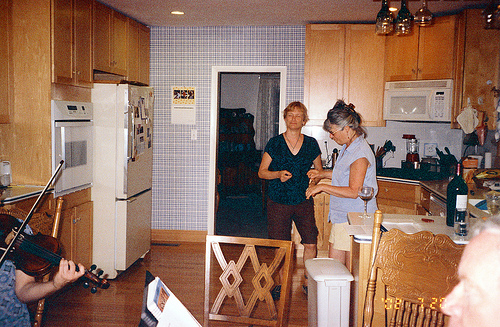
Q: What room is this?
A: It is a kitchen.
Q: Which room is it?
A: It is a kitchen.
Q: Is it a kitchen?
A: Yes, it is a kitchen.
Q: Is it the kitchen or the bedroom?
A: It is the kitchen.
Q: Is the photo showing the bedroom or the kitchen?
A: It is showing the kitchen.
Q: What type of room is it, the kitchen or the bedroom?
A: It is the kitchen.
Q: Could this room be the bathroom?
A: No, it is the kitchen.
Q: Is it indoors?
A: Yes, it is indoors.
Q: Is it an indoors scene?
A: Yes, it is indoors.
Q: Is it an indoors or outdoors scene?
A: It is indoors.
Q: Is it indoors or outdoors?
A: It is indoors.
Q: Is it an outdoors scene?
A: No, it is indoors.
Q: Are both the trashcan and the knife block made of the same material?
A: No, the trashcan is made of plastic and the knife block is made of wood.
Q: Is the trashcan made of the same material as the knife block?
A: No, the trashcan is made of plastic and the knife block is made of wood.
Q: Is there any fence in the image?
A: No, there are no fences.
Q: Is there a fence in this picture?
A: No, there are no fences.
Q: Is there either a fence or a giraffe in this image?
A: No, there are no fences or giraffes.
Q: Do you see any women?
A: Yes, there is a woman.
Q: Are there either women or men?
A: Yes, there is a woman.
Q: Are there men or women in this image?
A: Yes, there is a woman.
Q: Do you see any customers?
A: No, there are no customers.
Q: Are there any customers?
A: No, there are no customers.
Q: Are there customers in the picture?
A: No, there are no customers.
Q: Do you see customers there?
A: No, there are no customers.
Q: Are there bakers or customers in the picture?
A: No, there are no customers or bakers.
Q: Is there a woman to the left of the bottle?
A: Yes, there is a woman to the left of the bottle.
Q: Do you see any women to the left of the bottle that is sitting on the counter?
A: Yes, there is a woman to the left of the bottle.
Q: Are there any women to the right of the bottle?
A: No, the woman is to the left of the bottle.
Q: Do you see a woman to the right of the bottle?
A: No, the woman is to the left of the bottle.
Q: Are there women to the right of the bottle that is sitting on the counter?
A: No, the woman is to the left of the bottle.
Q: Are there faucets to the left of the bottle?
A: No, there is a woman to the left of the bottle.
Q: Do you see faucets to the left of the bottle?
A: No, there is a woman to the left of the bottle.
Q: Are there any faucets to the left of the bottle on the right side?
A: No, there is a woman to the left of the bottle.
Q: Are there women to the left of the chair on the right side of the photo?
A: Yes, there is a woman to the left of the chair.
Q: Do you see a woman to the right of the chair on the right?
A: No, the woman is to the left of the chair.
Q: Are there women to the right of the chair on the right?
A: No, the woman is to the left of the chair.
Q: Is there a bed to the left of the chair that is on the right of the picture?
A: No, there is a woman to the left of the chair.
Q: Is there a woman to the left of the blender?
A: Yes, there is a woman to the left of the blender.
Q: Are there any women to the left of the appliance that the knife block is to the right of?
A: Yes, there is a woman to the left of the blender.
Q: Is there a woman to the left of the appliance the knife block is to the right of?
A: Yes, there is a woman to the left of the blender.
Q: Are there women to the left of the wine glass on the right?
A: Yes, there is a woman to the left of the wine glass.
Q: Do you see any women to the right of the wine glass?
A: No, the woman is to the left of the wine glass.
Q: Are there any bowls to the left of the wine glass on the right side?
A: No, there is a woman to the left of the wine glass.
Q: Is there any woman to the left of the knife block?
A: Yes, there is a woman to the left of the knife block.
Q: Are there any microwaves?
A: Yes, there is a microwave.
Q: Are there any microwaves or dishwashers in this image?
A: Yes, there is a microwave.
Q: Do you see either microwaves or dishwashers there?
A: Yes, there is a microwave.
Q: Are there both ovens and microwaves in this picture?
A: Yes, there are both a microwave and an oven.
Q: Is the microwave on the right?
A: Yes, the microwave is on the right of the image.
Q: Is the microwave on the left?
A: No, the microwave is on the right of the image.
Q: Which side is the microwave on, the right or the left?
A: The microwave is on the right of the image.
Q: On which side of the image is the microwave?
A: The microwave is on the right of the image.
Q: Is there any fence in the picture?
A: No, there are no fences.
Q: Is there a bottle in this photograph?
A: Yes, there is a bottle.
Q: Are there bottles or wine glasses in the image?
A: Yes, there is a bottle.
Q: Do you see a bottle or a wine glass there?
A: Yes, there is a bottle.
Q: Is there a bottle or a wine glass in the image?
A: Yes, there is a bottle.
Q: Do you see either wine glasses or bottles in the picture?
A: Yes, there is a bottle.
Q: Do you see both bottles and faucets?
A: No, there is a bottle but no faucets.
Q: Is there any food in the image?
A: No, there is no food.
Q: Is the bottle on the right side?
A: Yes, the bottle is on the right of the image.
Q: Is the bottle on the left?
A: No, the bottle is on the right of the image.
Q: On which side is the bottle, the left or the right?
A: The bottle is on the right of the image.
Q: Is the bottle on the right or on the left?
A: The bottle is on the right of the image.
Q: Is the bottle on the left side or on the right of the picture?
A: The bottle is on the right of the image.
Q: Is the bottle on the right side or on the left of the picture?
A: The bottle is on the right of the image.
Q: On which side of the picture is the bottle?
A: The bottle is on the right of the image.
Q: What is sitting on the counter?
A: The bottle is sitting on the counter.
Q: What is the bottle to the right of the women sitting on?
A: The bottle is sitting on the counter.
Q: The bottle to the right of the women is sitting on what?
A: The bottle is sitting on the counter.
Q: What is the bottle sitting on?
A: The bottle is sitting on the counter.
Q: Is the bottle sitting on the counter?
A: Yes, the bottle is sitting on the counter.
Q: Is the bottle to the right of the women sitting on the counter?
A: Yes, the bottle is sitting on the counter.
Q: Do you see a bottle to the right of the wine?
A: Yes, there is a bottle to the right of the wine.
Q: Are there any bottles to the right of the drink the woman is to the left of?
A: Yes, there is a bottle to the right of the wine.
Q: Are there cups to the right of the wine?
A: No, there is a bottle to the right of the wine.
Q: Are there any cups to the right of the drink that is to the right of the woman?
A: No, there is a bottle to the right of the wine.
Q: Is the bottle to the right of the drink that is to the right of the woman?
A: Yes, the bottle is to the right of the wine.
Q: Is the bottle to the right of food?
A: No, the bottle is to the right of the wine.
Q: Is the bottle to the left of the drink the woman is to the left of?
A: No, the bottle is to the right of the wine.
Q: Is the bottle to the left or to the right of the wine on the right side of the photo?
A: The bottle is to the right of the wine.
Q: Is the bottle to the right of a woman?
A: Yes, the bottle is to the right of a woman.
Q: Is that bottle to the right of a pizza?
A: No, the bottle is to the right of a woman.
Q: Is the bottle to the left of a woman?
A: No, the bottle is to the right of a woman.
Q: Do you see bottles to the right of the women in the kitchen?
A: Yes, there is a bottle to the right of the women.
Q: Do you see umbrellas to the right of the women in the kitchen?
A: No, there is a bottle to the right of the women.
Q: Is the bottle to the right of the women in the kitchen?
A: Yes, the bottle is to the right of the women.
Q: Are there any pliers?
A: No, there are no pliers.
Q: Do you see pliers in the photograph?
A: No, there are no pliers.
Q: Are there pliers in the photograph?
A: No, there are no pliers.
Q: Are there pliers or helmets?
A: No, there are no pliers or helmets.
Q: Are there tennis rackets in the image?
A: No, there are no tennis rackets.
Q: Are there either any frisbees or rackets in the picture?
A: No, there are no rackets or frisbees.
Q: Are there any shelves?
A: No, there are no shelves.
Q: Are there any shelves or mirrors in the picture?
A: No, there are no shelves or mirrors.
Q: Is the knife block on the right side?
A: Yes, the knife block is on the right of the image.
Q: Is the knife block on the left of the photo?
A: No, the knife block is on the right of the image.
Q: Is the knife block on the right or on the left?
A: The knife block is on the right of the image.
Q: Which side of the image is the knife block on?
A: The knife block is on the right of the image.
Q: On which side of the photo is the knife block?
A: The knife block is on the right of the image.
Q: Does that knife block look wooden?
A: Yes, the knife block is wooden.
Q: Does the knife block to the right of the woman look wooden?
A: Yes, the knife block is wooden.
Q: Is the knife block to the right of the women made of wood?
A: Yes, the knife block is made of wood.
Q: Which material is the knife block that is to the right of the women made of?
A: The knife block is made of wood.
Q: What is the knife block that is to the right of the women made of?
A: The knife block is made of wood.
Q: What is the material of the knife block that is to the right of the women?
A: The knife block is made of wood.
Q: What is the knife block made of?
A: The knife block is made of wood.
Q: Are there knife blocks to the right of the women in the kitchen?
A: Yes, there is a knife block to the right of the women.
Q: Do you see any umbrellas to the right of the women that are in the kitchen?
A: No, there is a knife block to the right of the women.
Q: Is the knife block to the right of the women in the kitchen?
A: Yes, the knife block is to the right of the women.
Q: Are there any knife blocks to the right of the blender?
A: Yes, there is a knife block to the right of the blender.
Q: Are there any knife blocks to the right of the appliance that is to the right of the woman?
A: Yes, there is a knife block to the right of the blender.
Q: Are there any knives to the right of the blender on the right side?
A: No, there is a knife block to the right of the blender.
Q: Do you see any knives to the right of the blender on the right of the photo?
A: No, there is a knife block to the right of the blender.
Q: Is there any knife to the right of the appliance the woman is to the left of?
A: No, there is a knife block to the right of the blender.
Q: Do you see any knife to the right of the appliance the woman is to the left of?
A: No, there is a knife block to the right of the blender.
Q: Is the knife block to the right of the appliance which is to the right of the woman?
A: Yes, the knife block is to the right of the blender.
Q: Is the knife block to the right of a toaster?
A: No, the knife block is to the right of the blender.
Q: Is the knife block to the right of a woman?
A: Yes, the knife block is to the right of a woman.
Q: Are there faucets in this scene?
A: No, there are no faucets.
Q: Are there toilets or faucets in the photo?
A: No, there are no faucets or toilets.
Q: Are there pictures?
A: No, there are no pictures.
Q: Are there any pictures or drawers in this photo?
A: No, there are no pictures or drawers.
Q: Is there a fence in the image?
A: No, there are no fences.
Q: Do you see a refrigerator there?
A: Yes, there is a refrigerator.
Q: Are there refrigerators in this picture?
A: Yes, there is a refrigerator.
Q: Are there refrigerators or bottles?
A: Yes, there is a refrigerator.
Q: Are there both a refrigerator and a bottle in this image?
A: Yes, there are both a refrigerator and a bottle.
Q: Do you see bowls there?
A: No, there are no bowls.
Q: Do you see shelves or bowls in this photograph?
A: No, there are no bowls or shelves.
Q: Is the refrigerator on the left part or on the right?
A: The refrigerator is on the left of the image.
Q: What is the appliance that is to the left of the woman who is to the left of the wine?
A: The appliance is a refrigerator.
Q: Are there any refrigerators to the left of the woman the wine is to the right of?
A: Yes, there is a refrigerator to the left of the woman.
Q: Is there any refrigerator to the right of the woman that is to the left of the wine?
A: No, the refrigerator is to the left of the woman.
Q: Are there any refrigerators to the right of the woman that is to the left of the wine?
A: No, the refrigerator is to the left of the woman.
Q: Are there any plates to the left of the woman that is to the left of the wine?
A: No, there is a refrigerator to the left of the woman.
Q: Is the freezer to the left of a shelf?
A: No, the freezer is to the left of a woman.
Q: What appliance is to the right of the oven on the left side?
A: The appliance is a refrigerator.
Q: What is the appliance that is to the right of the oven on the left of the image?
A: The appliance is a refrigerator.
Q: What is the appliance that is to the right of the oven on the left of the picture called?
A: The appliance is a refrigerator.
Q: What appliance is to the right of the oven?
A: The appliance is a refrigerator.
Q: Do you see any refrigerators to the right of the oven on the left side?
A: Yes, there is a refrigerator to the right of the oven.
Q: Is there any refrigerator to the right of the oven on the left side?
A: Yes, there is a refrigerator to the right of the oven.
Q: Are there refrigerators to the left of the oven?
A: No, the refrigerator is to the right of the oven.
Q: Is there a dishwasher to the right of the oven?
A: No, there is a refrigerator to the right of the oven.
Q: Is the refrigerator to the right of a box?
A: No, the refrigerator is to the right of an oven.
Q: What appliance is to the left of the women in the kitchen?
A: The appliance is a refrigerator.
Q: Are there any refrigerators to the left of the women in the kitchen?
A: Yes, there is a refrigerator to the left of the women.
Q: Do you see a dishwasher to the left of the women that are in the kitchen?
A: No, there is a refrigerator to the left of the women.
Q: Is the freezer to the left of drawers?
A: No, the freezer is to the left of the women.